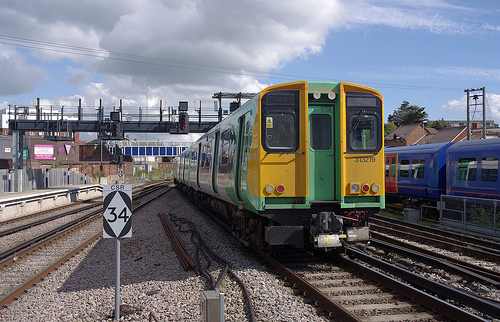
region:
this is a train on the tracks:
[165, 80, 400, 252]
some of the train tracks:
[333, 227, 488, 317]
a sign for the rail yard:
[87, 163, 147, 316]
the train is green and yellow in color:
[243, 75, 389, 264]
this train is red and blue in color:
[390, 135, 495, 249]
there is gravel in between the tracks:
[101, 197, 223, 319]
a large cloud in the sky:
[81, 8, 293, 88]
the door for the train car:
[308, 102, 336, 202]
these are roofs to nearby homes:
[402, 105, 494, 140]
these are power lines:
[36, 41, 267, 84]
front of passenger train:
[273, 90, 380, 201]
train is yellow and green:
[267, 177, 449, 214]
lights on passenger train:
[268, 183, 420, 190]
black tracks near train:
[303, 218, 481, 271]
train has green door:
[311, 110, 336, 189]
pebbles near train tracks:
[61, 266, 161, 300]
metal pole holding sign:
[113, 248, 138, 297]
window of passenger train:
[218, 128, 250, 203]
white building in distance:
[127, 143, 179, 161]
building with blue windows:
[137, 148, 224, 169]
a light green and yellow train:
[172, 80, 387, 256]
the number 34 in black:
[106, 204, 130, 223]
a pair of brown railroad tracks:
[0, 176, 175, 311]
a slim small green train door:
[306, 103, 338, 200]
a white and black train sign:
[103, 182, 133, 320]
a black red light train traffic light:
[178, 111, 189, 133]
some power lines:
[0, 29, 491, 103]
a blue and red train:
[381, 139, 498, 201]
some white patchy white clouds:
[0, 0, 349, 101]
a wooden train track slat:
[319, 282, 380, 293]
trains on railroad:
[71, 72, 498, 319]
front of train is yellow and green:
[249, 78, 391, 233]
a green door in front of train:
[310, 96, 341, 207]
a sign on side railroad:
[97, 177, 138, 314]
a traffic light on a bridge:
[168, 99, 197, 142]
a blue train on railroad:
[393, 132, 497, 216]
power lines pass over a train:
[5, 36, 493, 97]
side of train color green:
[167, 95, 261, 209]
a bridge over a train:
[11, 100, 222, 134]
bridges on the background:
[111, 137, 183, 169]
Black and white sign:
[101, 181, 133, 239]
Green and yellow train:
[255, 80, 384, 215]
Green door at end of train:
[301, 101, 338, 206]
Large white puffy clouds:
[7, 5, 341, 87]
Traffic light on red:
[175, 110, 191, 134]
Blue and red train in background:
[387, 140, 495, 190]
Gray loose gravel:
[19, 290, 104, 317]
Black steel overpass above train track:
[7, 104, 204, 134]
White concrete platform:
[3, 189, 53, 215]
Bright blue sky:
[320, 3, 496, 77]